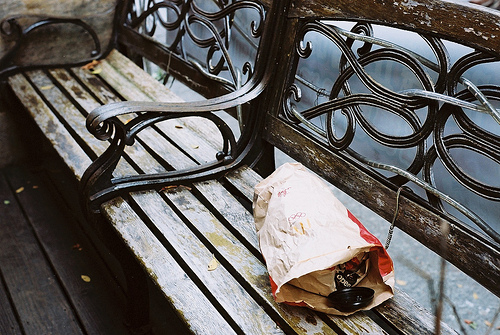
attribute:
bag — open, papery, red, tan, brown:
[253, 165, 398, 321]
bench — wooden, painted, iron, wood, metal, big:
[22, 0, 499, 335]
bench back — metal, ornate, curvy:
[267, 14, 497, 140]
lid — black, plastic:
[328, 286, 374, 314]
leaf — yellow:
[78, 268, 94, 285]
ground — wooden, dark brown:
[3, 159, 127, 320]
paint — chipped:
[185, 200, 234, 243]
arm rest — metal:
[86, 77, 279, 198]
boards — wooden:
[17, 211, 82, 333]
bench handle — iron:
[79, 94, 262, 123]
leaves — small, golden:
[7, 181, 101, 302]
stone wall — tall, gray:
[148, 1, 490, 183]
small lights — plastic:
[147, 54, 177, 89]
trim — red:
[269, 276, 286, 304]